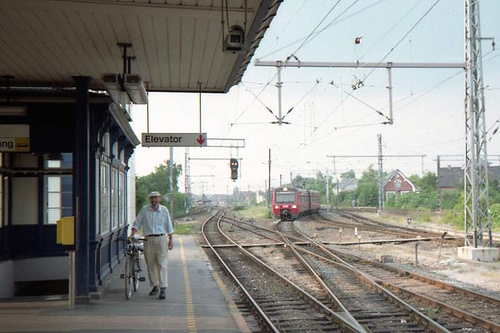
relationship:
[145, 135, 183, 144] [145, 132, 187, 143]
elevator says elevator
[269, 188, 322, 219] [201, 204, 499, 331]
engine coming down tracks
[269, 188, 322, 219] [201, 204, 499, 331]
engine down tracks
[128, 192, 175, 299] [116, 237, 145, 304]
he rolling bicycle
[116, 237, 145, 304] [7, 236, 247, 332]
bicycle rolling down platform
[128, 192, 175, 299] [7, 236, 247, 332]
he on platform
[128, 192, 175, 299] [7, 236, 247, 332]
he standing on platform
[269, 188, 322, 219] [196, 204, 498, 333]
engine on tracks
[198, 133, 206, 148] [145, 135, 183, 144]
arrow on elevator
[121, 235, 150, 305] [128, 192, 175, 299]
bicycle next to he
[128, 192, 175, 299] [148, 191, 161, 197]
he wearing cap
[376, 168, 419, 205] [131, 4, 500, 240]
house in background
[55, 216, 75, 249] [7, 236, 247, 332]
box near platform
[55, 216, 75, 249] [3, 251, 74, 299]
box near entrance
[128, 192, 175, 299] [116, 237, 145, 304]
he with bicycle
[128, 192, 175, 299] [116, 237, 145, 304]
he walking with bicycle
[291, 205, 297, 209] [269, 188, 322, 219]
headlight on engine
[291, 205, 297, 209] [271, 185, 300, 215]
headlight on front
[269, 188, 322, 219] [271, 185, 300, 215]
engine has front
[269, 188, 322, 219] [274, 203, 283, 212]
engine has headlight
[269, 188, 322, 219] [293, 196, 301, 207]
engine has headlight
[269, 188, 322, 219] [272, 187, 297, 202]
engine has window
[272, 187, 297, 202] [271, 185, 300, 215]
window in front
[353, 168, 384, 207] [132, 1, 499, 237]
tree in distance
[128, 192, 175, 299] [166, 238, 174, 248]
he has hand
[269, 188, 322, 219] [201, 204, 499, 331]
engine around tracks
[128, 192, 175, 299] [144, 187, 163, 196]
he wearing cap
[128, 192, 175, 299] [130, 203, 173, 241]
he wearing shirt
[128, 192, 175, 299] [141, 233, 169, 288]
he wearing pants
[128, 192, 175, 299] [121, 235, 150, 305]
he holding bicycle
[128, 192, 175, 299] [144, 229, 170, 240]
he wearing belt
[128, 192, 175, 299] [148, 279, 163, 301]
he wearing shoes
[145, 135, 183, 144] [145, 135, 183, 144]
elevator on elevator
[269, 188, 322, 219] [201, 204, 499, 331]
engine on tracks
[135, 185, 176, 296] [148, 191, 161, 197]
he wears cap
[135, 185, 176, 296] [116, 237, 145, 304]
we walks with bicycle